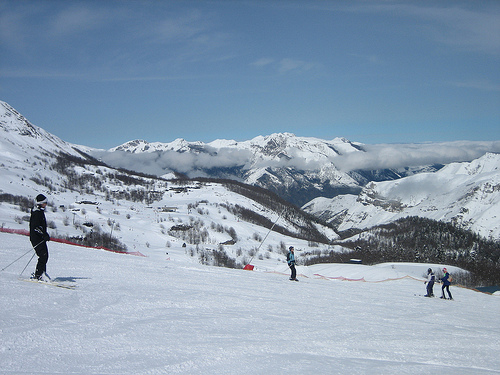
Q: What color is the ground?
A: White.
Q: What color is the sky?
A: Blue.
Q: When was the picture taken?
A: In the day time.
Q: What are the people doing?
A: Skiing.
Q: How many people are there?
A: 4.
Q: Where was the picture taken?
A: On the ski slopes.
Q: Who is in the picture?
A: Skiers.